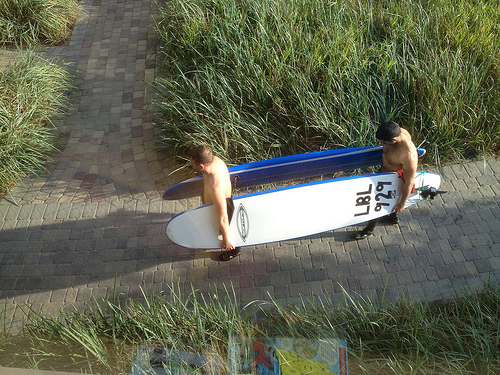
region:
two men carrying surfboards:
[171, 145, 440, 295]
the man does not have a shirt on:
[186, 137, 253, 242]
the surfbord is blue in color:
[207, 137, 397, 173]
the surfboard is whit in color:
[245, 183, 392, 255]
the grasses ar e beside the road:
[303, 58, 463, 123]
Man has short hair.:
[385, 119, 397, 134]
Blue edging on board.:
[190, 183, 398, 200]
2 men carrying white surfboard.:
[203, 196, 415, 256]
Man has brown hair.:
[183, 136, 223, 173]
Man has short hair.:
[186, 143, 228, 175]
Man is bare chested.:
[188, 176, 235, 193]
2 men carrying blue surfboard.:
[174, 135, 417, 161]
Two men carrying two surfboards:
[162, 120, 443, 260]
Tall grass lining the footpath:
[161, 4, 493, 159]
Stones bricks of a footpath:
[5, 212, 163, 319]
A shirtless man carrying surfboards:
[188, 140, 241, 261]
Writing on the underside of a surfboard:
[353, 179, 390, 217]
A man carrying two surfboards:
[350, 122, 418, 242]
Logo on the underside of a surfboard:
[235, 200, 250, 242]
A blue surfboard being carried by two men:
[161, 142, 428, 200]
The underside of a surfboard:
[167, 168, 454, 252]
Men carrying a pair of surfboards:
[161, 119, 441, 262]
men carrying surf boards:
[160, 122, 447, 262]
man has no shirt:
[202, 162, 231, 205]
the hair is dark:
[377, 121, 400, 143]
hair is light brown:
[190, 143, 212, 160]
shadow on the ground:
[0, 206, 210, 301]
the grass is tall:
[152, 0, 499, 174]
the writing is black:
[355, 180, 390, 217]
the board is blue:
[162, 145, 432, 200]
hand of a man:
[393, 203, 403, 213]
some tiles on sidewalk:
[77, 49, 133, 120]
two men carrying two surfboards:
[157, 116, 442, 261]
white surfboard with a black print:
[165, 170, 444, 249]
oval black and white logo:
[232, 202, 254, 242]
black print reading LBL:
[349, 183, 372, 219]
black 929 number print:
[373, 179, 395, 211]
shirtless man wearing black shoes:
[187, 141, 238, 262]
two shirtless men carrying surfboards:
[159, 115, 454, 262]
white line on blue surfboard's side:
[155, 140, 430, 202]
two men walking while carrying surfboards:
[159, 117, 444, 262]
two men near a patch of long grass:
[139, 2, 499, 263]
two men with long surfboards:
[162, 119, 445, 259]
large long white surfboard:
[164, 170, 449, 250]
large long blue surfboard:
[157, 143, 425, 204]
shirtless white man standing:
[188, 143, 241, 260]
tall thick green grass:
[157, 4, 497, 171]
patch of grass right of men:
[165, 3, 492, 144]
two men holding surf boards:
[146, 127, 458, 248]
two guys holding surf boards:
[143, 127, 461, 237]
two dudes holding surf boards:
[128, 102, 457, 248]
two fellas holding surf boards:
[153, 104, 444, 247]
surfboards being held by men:
[164, 97, 444, 251]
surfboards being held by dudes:
[131, 113, 471, 268]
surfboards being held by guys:
[148, 106, 436, 261]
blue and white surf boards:
[156, 148, 456, 255]